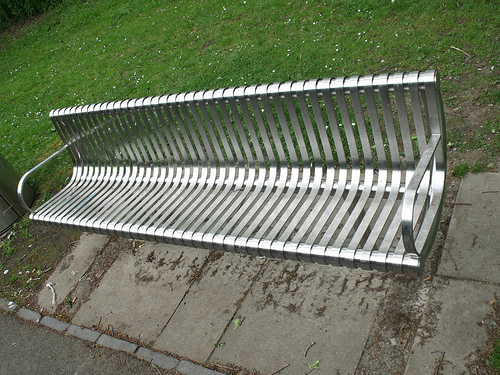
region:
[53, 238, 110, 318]
line on old concrete pad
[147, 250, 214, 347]
line on old concrete pad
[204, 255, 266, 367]
line on old concrete pad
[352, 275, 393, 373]
line on old concrete pad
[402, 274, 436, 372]
line on old concrete pad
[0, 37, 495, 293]
this is a bench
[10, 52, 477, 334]
the bench is metal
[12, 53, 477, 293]
the bench is silver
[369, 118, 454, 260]
silver arm on bench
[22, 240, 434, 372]
cement under the bench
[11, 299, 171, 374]
pavers next to bench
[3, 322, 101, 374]
concrete next to pavers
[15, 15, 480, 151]
grass behind the bench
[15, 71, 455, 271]
slats on the bench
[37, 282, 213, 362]
debris on the ground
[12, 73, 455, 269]
silver colored seating bench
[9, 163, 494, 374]
cement patio under bench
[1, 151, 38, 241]
trash can receptacle next to bench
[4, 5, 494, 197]
field of grassy land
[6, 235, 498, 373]
brown leaves on patio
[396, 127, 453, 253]
silver handles on bench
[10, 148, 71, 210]
bench with silver handle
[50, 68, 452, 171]
back part of bench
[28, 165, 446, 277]
seat of bench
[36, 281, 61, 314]
garbage on patio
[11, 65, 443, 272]
a long steel bench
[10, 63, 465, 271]
a shiny park seat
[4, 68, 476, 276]
metal park bench outside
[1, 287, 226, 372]
a road with a brick trim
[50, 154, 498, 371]
concrete slabs under a bench seat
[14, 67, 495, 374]
bench on a concrete slab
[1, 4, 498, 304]
a grassy park behind a bench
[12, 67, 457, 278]
metal seat in public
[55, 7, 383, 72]
leaves scattered across the grass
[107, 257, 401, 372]
dirty broken concrete blocks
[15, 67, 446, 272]
long metal bench on concrete platform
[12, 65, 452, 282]
bench composed of silver vertical strips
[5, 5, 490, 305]
green grass covered with little white flowers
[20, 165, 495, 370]
square and rectangular panels of concrete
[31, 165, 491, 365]
brown and dried growth over panels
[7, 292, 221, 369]
bricks between pavement and concrete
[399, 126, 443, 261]
curved armrest at end of bench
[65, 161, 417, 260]
metal supports seen through slats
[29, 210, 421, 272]
,metal wrapped under metal pole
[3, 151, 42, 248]
bottom edge of container next to bench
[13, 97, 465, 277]
a silver bench in the park.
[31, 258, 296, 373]
The ground is made of concrete.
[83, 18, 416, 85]
The grass is green.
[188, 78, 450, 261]
The bench is made of steel.